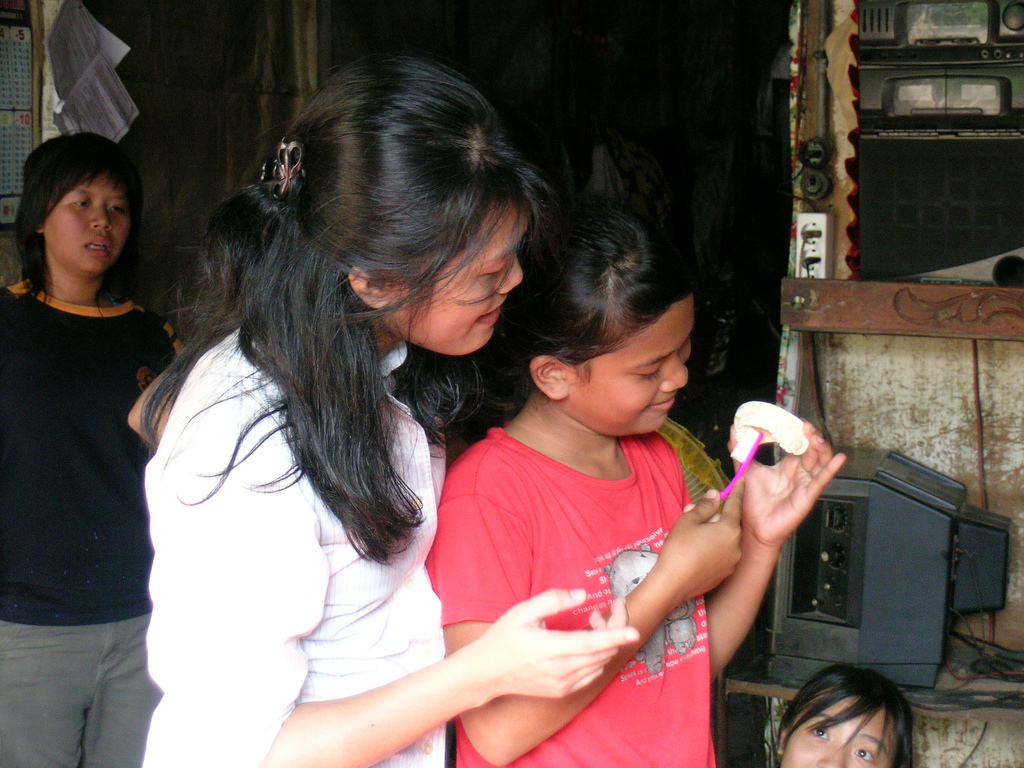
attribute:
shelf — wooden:
[788, 274, 1015, 346]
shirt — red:
[490, 472, 614, 611]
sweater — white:
[203, 485, 322, 680]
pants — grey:
[2, 618, 149, 759]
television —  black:
[769, 471, 1003, 690]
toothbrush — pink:
[711, 418, 768, 503]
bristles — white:
[730, 418, 767, 470]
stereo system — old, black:
[840, 3, 992, 282]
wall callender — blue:
[4, 18, 44, 230]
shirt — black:
[2, 279, 184, 627]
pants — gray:
[4, 618, 165, 765]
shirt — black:
[2, 282, 199, 639]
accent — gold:
[130, 363, 157, 398]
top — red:
[423, 430, 722, 765]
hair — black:
[153, 45, 566, 570]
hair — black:
[789, 648, 928, 765]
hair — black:
[447, 199, 707, 446]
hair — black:
[15, 127, 154, 305]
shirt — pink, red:
[421, 415, 726, 765]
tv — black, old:
[763, 451, 1012, 700]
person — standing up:
[413, 202, 854, 764]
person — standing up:
[434, 204, 731, 760]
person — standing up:
[125, 68, 616, 764]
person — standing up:
[0, 115, 212, 762]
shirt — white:
[137, 372, 444, 753]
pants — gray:
[18, 627, 137, 744]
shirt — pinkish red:
[437, 448, 708, 762]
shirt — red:
[390, 416, 740, 766]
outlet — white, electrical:
[784, 203, 849, 290]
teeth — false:
[732, 394, 813, 468]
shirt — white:
[131, 325, 464, 764]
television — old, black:
[760, 446, 990, 699]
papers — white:
[39, 5, 150, 150]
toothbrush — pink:
[713, 422, 763, 503]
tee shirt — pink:
[427, 417, 743, 765]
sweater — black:
[2, 282, 184, 637]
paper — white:
[28, 5, 150, 112]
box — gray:
[764, 443, 991, 699]